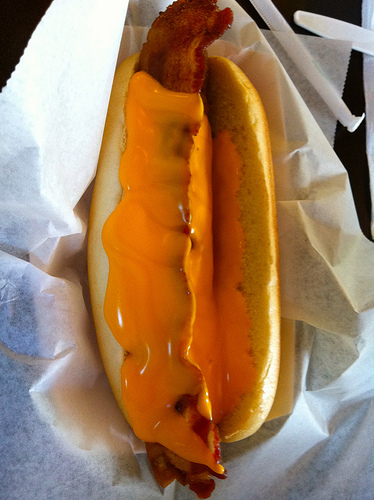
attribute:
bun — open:
[223, 81, 298, 273]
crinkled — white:
[284, 122, 344, 271]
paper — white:
[267, 76, 322, 155]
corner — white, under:
[273, 12, 369, 119]